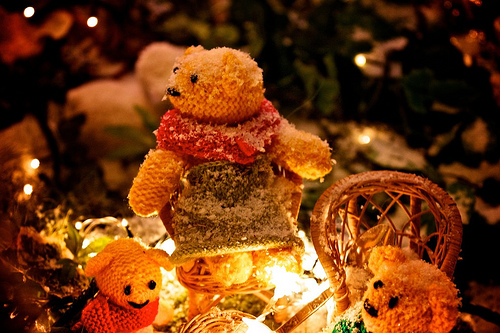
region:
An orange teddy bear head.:
[150, 23, 290, 129]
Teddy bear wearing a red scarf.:
[155, 96, 291, 160]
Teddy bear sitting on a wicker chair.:
[322, 172, 479, 326]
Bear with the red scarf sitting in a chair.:
[154, 23, 341, 298]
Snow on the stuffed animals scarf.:
[157, 104, 291, 162]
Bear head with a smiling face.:
[77, 239, 167, 317]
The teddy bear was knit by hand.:
[115, 43, 332, 221]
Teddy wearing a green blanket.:
[163, 145, 290, 267]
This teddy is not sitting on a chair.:
[40, 232, 185, 329]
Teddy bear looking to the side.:
[157, 35, 283, 115]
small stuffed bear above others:
[98, 25, 350, 289]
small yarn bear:
[49, 210, 181, 330]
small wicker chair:
[316, 139, 478, 319]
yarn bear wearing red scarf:
[46, 230, 173, 323]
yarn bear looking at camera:
[56, 215, 173, 331]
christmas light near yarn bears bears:
[254, 244, 322, 309]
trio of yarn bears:
[47, 40, 484, 332]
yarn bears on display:
[86, 41, 450, 332]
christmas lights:
[10, 142, 46, 200]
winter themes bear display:
[48, 27, 478, 330]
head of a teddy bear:
[147, 26, 281, 145]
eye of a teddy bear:
[189, 56, 202, 83]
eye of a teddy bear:
[155, 63, 182, 88]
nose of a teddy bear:
[160, 86, 197, 104]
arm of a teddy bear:
[117, 141, 202, 236]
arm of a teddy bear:
[280, 120, 337, 176]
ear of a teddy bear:
[68, 252, 144, 284]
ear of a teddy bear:
[125, 244, 190, 273]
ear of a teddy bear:
[359, 230, 410, 261]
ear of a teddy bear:
[417, 287, 478, 331]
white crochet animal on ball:
[128, 44, 331, 247]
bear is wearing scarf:
[146, 103, 288, 167]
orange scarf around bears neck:
[78, 292, 158, 332]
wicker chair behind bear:
[313, 173, 460, 313]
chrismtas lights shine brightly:
[3, 3, 369, 195]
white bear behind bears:
[8, 39, 198, 197]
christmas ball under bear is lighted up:
[102, 212, 347, 332]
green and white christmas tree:
[121, 2, 498, 249]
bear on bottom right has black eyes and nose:
[363, 274, 400, 321]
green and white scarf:
[333, 291, 373, 332]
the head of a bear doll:
[146, 47, 278, 120]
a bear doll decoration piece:
[124, 34, 322, 294]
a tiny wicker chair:
[302, 159, 466, 300]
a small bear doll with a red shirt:
[81, 243, 175, 329]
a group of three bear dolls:
[69, 32, 468, 331]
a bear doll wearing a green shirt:
[328, 247, 469, 330]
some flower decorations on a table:
[2, 165, 84, 331]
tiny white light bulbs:
[11, 134, 63, 204]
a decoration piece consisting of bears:
[41, 40, 468, 328]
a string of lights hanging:
[9, 4, 496, 80]